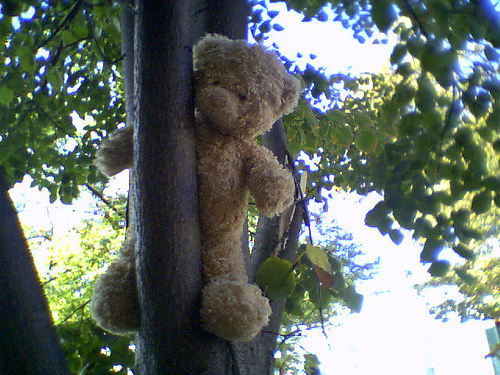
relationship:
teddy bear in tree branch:
[86, 29, 317, 350] [128, 3, 235, 373]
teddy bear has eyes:
[86, 29, 317, 350] [204, 74, 253, 106]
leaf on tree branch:
[253, 255, 301, 302] [241, 100, 319, 371]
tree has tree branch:
[1, 7, 494, 373] [128, 3, 235, 373]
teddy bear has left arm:
[86, 29, 317, 350] [249, 139, 296, 217]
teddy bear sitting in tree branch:
[86, 29, 317, 350] [128, 3, 235, 373]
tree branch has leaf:
[241, 100, 319, 371] [357, 130, 377, 152]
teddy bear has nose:
[86, 29, 317, 350] [201, 91, 228, 109]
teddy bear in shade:
[86, 29, 317, 350] [13, 3, 491, 374]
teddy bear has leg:
[86, 29, 317, 350] [193, 223, 272, 344]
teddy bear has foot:
[86, 29, 317, 350] [201, 283, 273, 339]